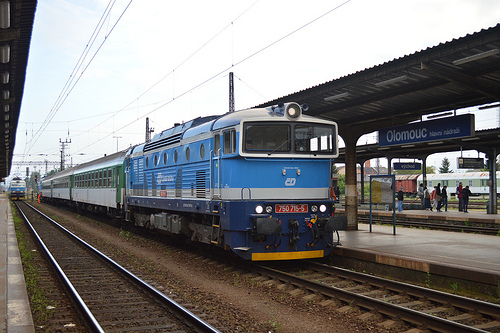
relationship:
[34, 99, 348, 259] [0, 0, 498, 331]
train in station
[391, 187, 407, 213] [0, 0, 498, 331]
person in station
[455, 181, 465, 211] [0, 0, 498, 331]
person in station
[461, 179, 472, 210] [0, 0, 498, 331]
person in station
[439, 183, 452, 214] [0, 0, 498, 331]
person in station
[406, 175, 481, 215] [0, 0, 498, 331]
people in station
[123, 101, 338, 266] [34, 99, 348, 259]
blue engine on train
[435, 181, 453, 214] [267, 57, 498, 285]
person at train station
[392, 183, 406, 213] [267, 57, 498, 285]
person at train station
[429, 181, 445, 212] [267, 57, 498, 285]
person at train station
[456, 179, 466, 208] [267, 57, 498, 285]
person at train station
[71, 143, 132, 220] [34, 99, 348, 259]
car on train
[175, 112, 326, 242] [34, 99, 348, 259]
car on train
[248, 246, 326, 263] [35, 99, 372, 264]
yellow bumper on train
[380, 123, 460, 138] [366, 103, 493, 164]
lettering on sign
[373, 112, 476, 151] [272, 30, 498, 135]
blue sign hanging from roof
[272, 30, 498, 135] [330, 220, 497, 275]
roof over platform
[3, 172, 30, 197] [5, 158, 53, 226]
train in background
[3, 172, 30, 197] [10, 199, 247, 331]
train coming down tracks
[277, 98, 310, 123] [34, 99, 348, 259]
top light on train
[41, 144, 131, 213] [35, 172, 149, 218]
cars of train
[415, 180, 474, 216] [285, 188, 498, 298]
people waiting on platform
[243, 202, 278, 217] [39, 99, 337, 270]
headlight on train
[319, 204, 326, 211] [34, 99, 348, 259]
headlight on train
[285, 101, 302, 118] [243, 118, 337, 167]
headlight above windows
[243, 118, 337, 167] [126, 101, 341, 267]
windows of train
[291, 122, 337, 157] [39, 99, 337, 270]
window of train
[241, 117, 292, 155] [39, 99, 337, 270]
window of train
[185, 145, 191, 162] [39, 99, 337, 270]
window of train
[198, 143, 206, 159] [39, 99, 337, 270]
window of train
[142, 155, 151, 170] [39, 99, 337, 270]
window of train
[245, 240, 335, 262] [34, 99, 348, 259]
stripe on train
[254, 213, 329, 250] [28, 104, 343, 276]
wires on front of train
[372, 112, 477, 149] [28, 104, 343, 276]
sign to right of train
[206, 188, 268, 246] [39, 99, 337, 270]
edge of train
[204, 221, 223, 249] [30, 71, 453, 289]
part of train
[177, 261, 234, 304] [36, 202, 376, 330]
part of ground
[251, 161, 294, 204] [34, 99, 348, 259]
part of train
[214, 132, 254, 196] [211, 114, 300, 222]
edge of train